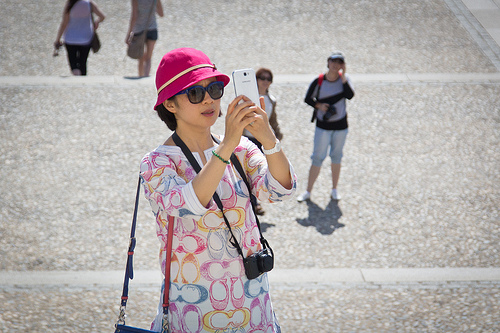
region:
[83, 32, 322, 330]
the woman with camera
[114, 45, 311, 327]
the woman using phone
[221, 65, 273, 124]
phone is white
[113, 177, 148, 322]
strap of the bag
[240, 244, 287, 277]
the camera with strap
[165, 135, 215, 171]
the strap of camera is black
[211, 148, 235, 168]
bracelet on the arm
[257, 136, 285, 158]
the white watch on the wrist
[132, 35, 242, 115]
woman wearing pink hat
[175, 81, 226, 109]
woman wearing the sunglasses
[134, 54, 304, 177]
face of the person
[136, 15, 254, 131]
face of the girl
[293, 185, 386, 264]
shadow of the person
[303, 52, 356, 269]
shadow of the girl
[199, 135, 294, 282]
a camera in front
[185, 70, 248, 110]
spects wearing by girl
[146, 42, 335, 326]
a beautiful girl standing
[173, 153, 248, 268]
a tag of the camera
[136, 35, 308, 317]
a cute girl with mobile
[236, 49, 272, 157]
a girl holding mobile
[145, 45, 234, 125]
a woman wearing a pink hat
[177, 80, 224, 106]
a person wearing sunglasses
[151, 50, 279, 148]
a woman holding a smartphone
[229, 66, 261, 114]
a white smart phone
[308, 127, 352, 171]
a person wearing blue shorts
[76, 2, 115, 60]
a woman carrying a handbag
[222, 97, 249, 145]
the right hand of a person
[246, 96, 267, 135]
the left hand of a person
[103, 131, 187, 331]
a handbag on a woman's shoulder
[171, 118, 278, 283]
a woman with a camera around her neck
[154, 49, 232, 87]
pink hat on woman's head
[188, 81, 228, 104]
blue sunglasses on woman's face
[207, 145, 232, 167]
green bracelet on woman's wrist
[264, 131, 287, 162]
white watch on woman's wrist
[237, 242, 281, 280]
black camera on woman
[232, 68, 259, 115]
white camera cell phone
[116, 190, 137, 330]
blue strap on woman's purse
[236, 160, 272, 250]
black strap on woman's camera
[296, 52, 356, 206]
woman standing in background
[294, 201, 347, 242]
woman in background's shadow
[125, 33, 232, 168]
a woman wearing blue sunglasses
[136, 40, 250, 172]
a woman wearing a pink hat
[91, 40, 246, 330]
a woman wearing a purse on her shoulder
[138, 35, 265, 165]
a woman taking a photo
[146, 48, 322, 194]
a woman wearing a watch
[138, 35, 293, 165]
a woman holding a cellphone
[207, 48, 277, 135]
a white cell phone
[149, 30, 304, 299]
a woman wearing a camera around her neck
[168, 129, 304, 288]
a black camera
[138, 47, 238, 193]
a woman wearing a bracelet